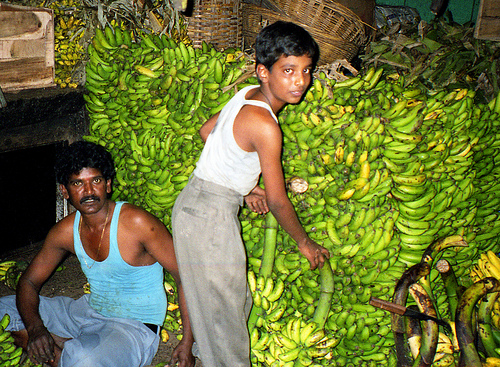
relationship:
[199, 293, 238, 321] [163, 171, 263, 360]
part of trouser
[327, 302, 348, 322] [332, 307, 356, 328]
part of banana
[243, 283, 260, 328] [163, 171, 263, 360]
edge of trouser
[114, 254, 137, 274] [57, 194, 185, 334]
edge of vest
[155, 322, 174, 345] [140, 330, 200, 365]
part of floor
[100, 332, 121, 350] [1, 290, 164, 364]
part of jeans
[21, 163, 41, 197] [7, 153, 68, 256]
part of hollow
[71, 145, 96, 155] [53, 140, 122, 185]
part of hairs